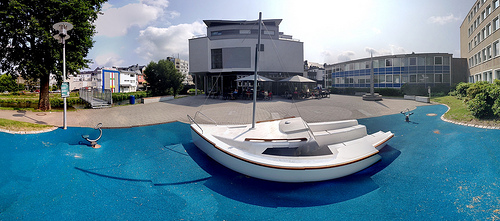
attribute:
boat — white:
[191, 111, 393, 190]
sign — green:
[54, 78, 81, 100]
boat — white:
[173, 107, 403, 182]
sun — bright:
[268, 1, 393, 50]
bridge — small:
[70, 82, 115, 110]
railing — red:
[241, 134, 311, 144]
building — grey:
[314, 55, 472, 92]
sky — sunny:
[1, 2, 476, 83]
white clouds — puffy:
[89, 1, 206, 65]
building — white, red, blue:
[93, 1, 475, 126]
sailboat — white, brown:
[186, 112, 398, 193]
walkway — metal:
[73, 84, 115, 109]